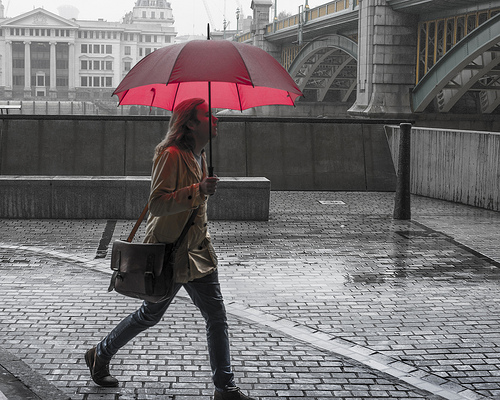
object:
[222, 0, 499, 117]
bridge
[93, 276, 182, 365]
right leg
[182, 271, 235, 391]
left leg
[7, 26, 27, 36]
detail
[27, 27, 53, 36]
detail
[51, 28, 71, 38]
detail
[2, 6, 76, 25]
detail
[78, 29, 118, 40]
detail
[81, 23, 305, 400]
person holding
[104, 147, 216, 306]
man carrying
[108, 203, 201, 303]
bag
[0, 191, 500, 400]
brick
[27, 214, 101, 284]
way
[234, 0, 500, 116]
metal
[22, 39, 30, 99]
pillars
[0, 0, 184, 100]
building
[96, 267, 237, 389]
brown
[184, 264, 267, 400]
person's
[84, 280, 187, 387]
person's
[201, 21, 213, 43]
tip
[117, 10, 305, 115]
top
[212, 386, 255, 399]
man has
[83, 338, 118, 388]
shoes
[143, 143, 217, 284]
jacket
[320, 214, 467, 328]
rain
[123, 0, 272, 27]
distance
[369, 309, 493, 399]
jackson mingus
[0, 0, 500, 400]
photo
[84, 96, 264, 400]
lady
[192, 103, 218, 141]
skinned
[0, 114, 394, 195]
wall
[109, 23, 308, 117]
color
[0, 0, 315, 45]
sky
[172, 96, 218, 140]
head is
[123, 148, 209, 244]
strap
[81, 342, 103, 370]
heel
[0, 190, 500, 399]
ground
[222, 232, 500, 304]
puddles of water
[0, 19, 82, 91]
twi white columns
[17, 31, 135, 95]
windows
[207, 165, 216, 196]
hand wrapped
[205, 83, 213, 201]
rod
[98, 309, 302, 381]
wrinkles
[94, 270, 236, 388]
pants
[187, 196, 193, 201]
black button